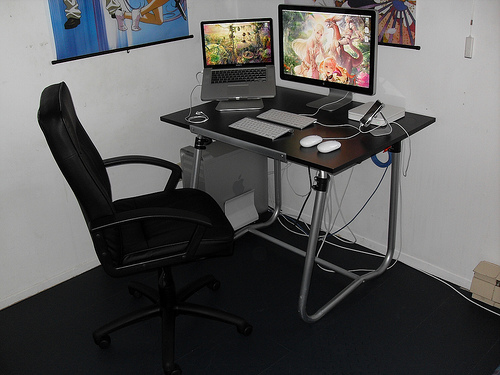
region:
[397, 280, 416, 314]
part of a floor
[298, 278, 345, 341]
part of a metal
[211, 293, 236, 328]
part of a stand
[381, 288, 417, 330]
part of a floor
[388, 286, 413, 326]
part of a floor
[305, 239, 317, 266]
part of a metal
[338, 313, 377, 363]
part of af loor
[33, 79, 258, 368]
a black desk chair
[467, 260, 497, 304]
a heating unit at the base of a wall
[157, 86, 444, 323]
a black and gray desk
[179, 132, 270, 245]
a computer on the floor next to a desk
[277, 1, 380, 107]
a computer monitor on a desk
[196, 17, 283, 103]
a silver colored laptop on a desk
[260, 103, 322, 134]
a keyboard on a desk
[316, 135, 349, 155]
a cordless mouse on a desk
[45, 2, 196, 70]
a poster on the wall next to a desk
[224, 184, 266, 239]
a piece of paper next to a computer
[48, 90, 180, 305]
this is a chair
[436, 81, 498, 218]
this is the wall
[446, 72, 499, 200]
the wall is white in color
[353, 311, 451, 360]
this is the floor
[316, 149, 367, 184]
this is a table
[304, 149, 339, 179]
the table is wooden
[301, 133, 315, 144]
this is the mouse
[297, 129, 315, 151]
the mouse is white in color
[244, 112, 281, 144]
this is a keyboard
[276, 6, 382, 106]
this is the screen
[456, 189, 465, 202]
part of a wall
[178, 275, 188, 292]
part of a seat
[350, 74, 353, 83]
part of a screen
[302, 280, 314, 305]
part of a table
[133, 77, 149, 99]
part of a wall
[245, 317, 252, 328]
part of a chair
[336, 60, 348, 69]
part of the screen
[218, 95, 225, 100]
part of a laptop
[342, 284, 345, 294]
part of a chair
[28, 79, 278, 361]
a black chair at a desk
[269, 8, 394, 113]
computer monitor on desk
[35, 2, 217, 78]
a blue poster on wall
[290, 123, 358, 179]
two yellow mouse for computer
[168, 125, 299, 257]
an apple computer on floor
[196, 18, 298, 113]
a laptop open on desk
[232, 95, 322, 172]
two keyboards on desk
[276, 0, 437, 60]
a poster behind the monitor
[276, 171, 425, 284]
white and black cords under desk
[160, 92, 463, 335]
a black and silver desk